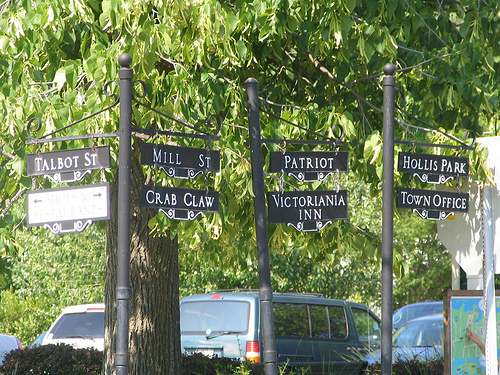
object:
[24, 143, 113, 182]
sign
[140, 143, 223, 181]
sign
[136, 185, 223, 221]
sign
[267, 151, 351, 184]
sign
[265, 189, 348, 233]
sign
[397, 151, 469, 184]
sign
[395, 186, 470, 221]
sign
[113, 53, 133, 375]
pole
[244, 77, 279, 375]
pole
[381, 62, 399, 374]
pole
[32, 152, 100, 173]
writing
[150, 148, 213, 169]
writing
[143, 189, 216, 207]
writing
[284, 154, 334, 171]
writing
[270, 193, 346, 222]
writing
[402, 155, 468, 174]
writing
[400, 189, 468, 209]
writing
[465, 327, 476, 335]
finger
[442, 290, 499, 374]
map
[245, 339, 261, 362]
tail light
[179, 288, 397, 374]
car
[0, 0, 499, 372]
tree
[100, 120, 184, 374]
trunk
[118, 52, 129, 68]
top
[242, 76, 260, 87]
top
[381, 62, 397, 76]
top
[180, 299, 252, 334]
glass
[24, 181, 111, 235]
sign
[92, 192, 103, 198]
arrows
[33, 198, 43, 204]
arrows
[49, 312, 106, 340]
window